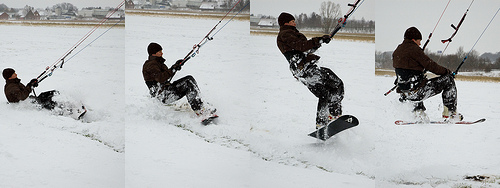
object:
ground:
[377, 69, 500, 187]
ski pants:
[290, 64, 353, 127]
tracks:
[42, 99, 110, 126]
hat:
[273, 12, 295, 26]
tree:
[313, 0, 344, 37]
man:
[272, 10, 362, 142]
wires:
[170, 0, 251, 77]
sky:
[121, 0, 247, 9]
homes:
[18, 9, 52, 21]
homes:
[253, 12, 278, 29]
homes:
[477, 52, 496, 65]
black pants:
[294, 67, 346, 123]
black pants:
[393, 75, 467, 114]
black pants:
[149, 74, 206, 119]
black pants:
[32, 90, 60, 114]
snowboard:
[301, 114, 367, 143]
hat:
[279, 12, 296, 26]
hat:
[403, 27, 423, 40]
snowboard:
[74, 101, 91, 119]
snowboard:
[393, 115, 485, 125]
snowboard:
[200, 114, 219, 126]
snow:
[0, 14, 497, 187]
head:
[278, 12, 299, 28]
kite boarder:
[382, 25, 485, 125]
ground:
[251, 30, 368, 184]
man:
[2, 66, 86, 121]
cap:
[145, 42, 165, 55]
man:
[141, 43, 218, 126]